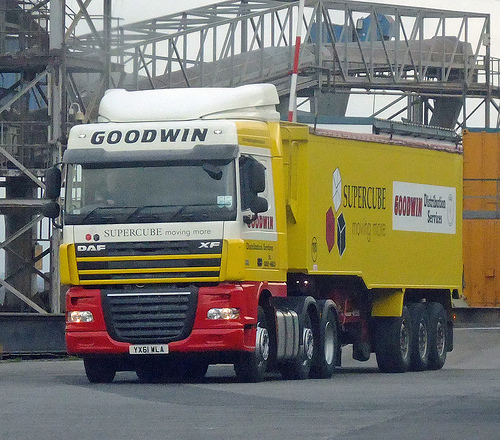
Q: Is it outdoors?
A: Yes, it is outdoors.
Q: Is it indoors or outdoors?
A: It is outdoors.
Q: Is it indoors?
A: No, it is outdoors.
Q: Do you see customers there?
A: No, there are no customers.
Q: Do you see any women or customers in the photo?
A: No, there are no customers or women.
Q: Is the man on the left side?
A: Yes, the man is on the left of the image.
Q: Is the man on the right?
A: No, the man is on the left of the image.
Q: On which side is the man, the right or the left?
A: The man is on the left of the image.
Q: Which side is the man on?
A: The man is on the left of the image.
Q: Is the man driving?
A: Yes, the man is driving.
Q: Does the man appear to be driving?
A: Yes, the man is driving.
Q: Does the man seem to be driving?
A: Yes, the man is driving.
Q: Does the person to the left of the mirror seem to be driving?
A: Yes, the man is driving.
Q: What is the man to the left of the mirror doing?
A: The man is driving.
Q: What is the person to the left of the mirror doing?
A: The man is driving.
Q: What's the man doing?
A: The man is driving.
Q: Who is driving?
A: The man is driving.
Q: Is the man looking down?
A: No, the man is driving.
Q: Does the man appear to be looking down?
A: No, the man is driving.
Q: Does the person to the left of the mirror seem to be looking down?
A: No, the man is driving.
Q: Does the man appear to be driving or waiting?
A: The man is driving.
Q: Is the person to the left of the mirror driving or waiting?
A: The man is driving.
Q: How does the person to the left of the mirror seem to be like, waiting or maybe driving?
A: The man is driving.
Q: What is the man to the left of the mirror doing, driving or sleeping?
A: The man is driving.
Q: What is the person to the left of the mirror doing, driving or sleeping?
A: The man is driving.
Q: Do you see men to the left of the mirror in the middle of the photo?
A: Yes, there is a man to the left of the mirror.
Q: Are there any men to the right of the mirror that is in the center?
A: No, the man is to the left of the mirror.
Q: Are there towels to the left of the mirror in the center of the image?
A: No, there is a man to the left of the mirror.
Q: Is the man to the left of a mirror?
A: Yes, the man is to the left of a mirror.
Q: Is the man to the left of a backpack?
A: No, the man is to the left of a mirror.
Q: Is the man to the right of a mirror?
A: No, the man is to the left of a mirror.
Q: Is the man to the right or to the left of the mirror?
A: The man is to the left of the mirror.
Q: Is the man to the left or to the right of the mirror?
A: The man is to the left of the mirror.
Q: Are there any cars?
A: No, there are no cars.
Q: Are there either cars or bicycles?
A: No, there are no cars or bicycles.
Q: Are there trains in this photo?
A: No, there are no trains.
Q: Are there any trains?
A: No, there are no trains.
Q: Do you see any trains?
A: No, there are no trains.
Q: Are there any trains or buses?
A: No, there are no trains or buses.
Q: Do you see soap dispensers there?
A: No, there are no soap dispensers.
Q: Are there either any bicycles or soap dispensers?
A: No, there are no soap dispensers or bicycles.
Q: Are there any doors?
A: Yes, there is a door.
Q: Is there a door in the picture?
A: Yes, there is a door.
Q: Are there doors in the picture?
A: Yes, there is a door.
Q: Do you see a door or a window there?
A: Yes, there is a door.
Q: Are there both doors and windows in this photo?
A: Yes, there are both a door and a window.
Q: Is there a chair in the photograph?
A: No, there are no chairs.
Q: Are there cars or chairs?
A: No, there are no chairs or cars.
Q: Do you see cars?
A: No, there are no cars.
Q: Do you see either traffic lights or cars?
A: No, there are no cars or traffic lights.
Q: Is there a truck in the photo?
A: Yes, there is a truck.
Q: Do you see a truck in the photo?
A: Yes, there is a truck.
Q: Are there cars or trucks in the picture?
A: Yes, there is a truck.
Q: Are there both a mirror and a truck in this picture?
A: Yes, there are both a truck and a mirror.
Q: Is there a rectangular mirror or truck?
A: Yes, there is a rectangular truck.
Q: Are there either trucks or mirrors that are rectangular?
A: Yes, the truck is rectangular.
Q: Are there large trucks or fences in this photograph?
A: Yes, there is a large truck.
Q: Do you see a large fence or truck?
A: Yes, there is a large truck.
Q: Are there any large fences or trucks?
A: Yes, there is a large truck.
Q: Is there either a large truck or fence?
A: Yes, there is a large truck.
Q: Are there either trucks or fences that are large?
A: Yes, the truck is large.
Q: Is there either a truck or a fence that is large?
A: Yes, the truck is large.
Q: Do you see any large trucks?
A: Yes, there is a large truck.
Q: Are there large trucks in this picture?
A: Yes, there is a large truck.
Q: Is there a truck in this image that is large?
A: Yes, there is a truck that is large.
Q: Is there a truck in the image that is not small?
A: Yes, there is a large truck.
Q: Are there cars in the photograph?
A: No, there are no cars.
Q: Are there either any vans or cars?
A: No, there are no cars or vans.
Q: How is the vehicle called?
A: The vehicle is a truck.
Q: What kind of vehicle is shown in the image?
A: The vehicle is a truck.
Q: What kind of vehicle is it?
A: The vehicle is a truck.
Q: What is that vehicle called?
A: This is a truck.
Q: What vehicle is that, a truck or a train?
A: This is a truck.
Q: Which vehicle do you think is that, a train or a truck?
A: This is a truck.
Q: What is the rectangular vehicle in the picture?
A: The vehicle is a truck.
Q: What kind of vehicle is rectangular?
A: The vehicle is a truck.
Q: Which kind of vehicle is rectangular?
A: The vehicle is a truck.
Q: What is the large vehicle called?
A: The vehicle is a truck.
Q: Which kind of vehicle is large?
A: The vehicle is a truck.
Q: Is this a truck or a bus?
A: This is a truck.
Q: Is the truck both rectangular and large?
A: Yes, the truck is rectangular and large.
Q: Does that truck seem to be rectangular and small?
A: No, the truck is rectangular but large.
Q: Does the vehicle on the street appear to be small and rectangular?
A: No, the truck is rectangular but large.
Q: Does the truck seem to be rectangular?
A: Yes, the truck is rectangular.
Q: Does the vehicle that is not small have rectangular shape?
A: Yes, the truck is rectangular.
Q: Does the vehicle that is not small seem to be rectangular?
A: Yes, the truck is rectangular.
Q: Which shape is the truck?
A: The truck is rectangular.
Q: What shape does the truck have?
A: The truck has rectangular shape.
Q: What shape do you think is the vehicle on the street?
A: The truck is rectangular.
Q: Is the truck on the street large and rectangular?
A: Yes, the truck is large and rectangular.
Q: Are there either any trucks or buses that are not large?
A: No, there is a truck but it is large.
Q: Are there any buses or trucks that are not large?
A: No, there is a truck but it is large.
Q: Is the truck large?
A: Yes, the truck is large.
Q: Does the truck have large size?
A: Yes, the truck is large.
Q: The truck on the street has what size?
A: The truck is large.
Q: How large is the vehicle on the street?
A: The truck is large.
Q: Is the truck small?
A: No, the truck is large.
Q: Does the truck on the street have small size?
A: No, the truck is large.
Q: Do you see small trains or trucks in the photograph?
A: No, there is a truck but it is large.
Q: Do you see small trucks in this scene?
A: No, there is a truck but it is large.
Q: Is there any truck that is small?
A: No, there is a truck but it is large.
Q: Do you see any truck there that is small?
A: No, there is a truck but it is large.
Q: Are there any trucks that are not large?
A: No, there is a truck but it is large.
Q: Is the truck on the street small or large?
A: The truck is large.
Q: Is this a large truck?
A: Yes, this is a large truck.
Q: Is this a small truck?
A: No, this is a large truck.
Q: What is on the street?
A: The truck is on the street.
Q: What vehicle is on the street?
A: The vehicle is a truck.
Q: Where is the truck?
A: The truck is on the street.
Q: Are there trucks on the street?
A: Yes, there is a truck on the street.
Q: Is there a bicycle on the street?
A: No, there is a truck on the street.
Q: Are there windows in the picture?
A: Yes, there is a window.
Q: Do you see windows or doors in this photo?
A: Yes, there is a window.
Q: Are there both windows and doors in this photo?
A: Yes, there are both a window and a door.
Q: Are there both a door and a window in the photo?
A: Yes, there are both a window and a door.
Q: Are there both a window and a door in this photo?
A: Yes, there are both a window and a door.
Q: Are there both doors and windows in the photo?
A: Yes, there are both a window and a door.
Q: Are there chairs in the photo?
A: No, there are no chairs.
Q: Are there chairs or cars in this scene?
A: No, there are no chairs or cars.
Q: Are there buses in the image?
A: No, there are no buses.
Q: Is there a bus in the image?
A: No, there are no buses.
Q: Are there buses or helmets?
A: No, there are no buses or helmets.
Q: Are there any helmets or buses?
A: No, there are no buses or helmets.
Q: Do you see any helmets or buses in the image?
A: No, there are no buses or helmets.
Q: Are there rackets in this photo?
A: No, there are no rackets.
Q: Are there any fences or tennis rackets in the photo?
A: No, there are no tennis rackets or fences.